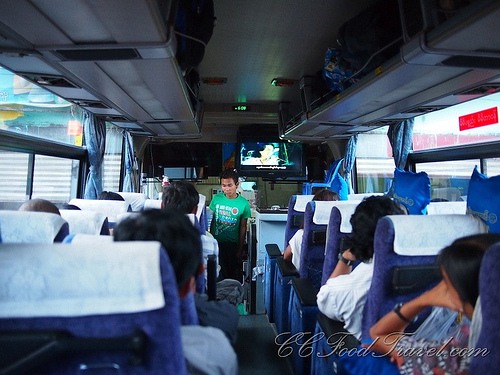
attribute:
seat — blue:
[286, 196, 308, 243]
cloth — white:
[73, 199, 127, 221]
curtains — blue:
[83, 117, 108, 197]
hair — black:
[165, 183, 196, 212]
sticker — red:
[456, 112, 497, 128]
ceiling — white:
[181, 14, 325, 125]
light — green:
[236, 105, 247, 109]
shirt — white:
[321, 251, 380, 327]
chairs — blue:
[276, 194, 497, 363]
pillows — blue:
[390, 174, 437, 205]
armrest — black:
[273, 255, 296, 278]